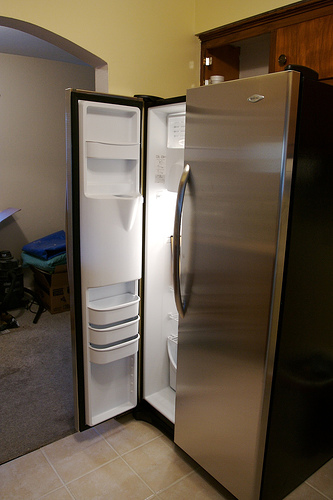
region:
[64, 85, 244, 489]
a refrigerator kept opened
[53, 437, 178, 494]
brown color floor tiles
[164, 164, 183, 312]
handle of the refrigerator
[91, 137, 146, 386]
white color rack of the refrigerator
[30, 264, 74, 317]
brown color box in the room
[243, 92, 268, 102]
brand name of the refrigerator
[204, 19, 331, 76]
wooden cupboard behind the refrigerator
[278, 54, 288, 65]
handle of the wardrobe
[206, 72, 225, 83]
white color box kept in the top of the refrigerator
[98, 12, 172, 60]
cream color coated wall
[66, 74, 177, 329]
The refrigerator door is open.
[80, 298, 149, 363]
White shelves in the refrigerator.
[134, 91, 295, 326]
The refrigerator is stainless steel.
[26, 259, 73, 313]
A cardboard box in the corner.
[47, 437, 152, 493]
The floor is tiled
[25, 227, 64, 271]
Blanket on top of the box.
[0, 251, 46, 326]
A vacuum cleaner next to the box.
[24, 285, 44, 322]
Black vacuum hose on the ground.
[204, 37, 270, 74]
The cabinet above the refrigerator is open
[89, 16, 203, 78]
The wall is yellow.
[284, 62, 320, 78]
black plastic hinge on silver door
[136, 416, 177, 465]
tan tile floor beside refrigerator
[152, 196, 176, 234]
light on inside refrigerator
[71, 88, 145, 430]
silver door with white plastic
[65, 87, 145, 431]
silver door open on refrigerator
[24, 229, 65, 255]
blue blanket folded by wall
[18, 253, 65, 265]
green blanket folded under blue one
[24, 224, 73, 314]
blue and green blankets folded on box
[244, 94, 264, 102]
silver nameplate on refrigerator door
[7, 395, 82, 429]
brown carpet by silver refrigerator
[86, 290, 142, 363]
three empty tubs on freezer door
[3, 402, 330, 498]
mock tile linoleum under fridge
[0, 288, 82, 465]
grey carpeting behind fridge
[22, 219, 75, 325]
tubs and bags stacked against wall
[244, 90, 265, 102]
manufacturer logo on fridge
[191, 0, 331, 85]
wooden "overhead cabinets" above fridge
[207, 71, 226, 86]
small white plastic cup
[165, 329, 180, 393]
bottom drawer in freezer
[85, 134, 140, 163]
white tub on top of freezer door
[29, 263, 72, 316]
cardboard box on floor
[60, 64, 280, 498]
a stainless steel fridge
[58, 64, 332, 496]
a black and silver fridge and freezer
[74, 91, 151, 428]
freezer door with shelves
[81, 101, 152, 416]
white interior of a freezer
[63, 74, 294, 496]
side by side fridge freezer combo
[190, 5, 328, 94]
brown cupboard above fridge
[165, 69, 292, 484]
stainless steel fridge door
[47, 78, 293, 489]
opened freezer door on fridge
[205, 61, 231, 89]
cup sitting in cupboard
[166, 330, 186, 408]
white drawer in freezer